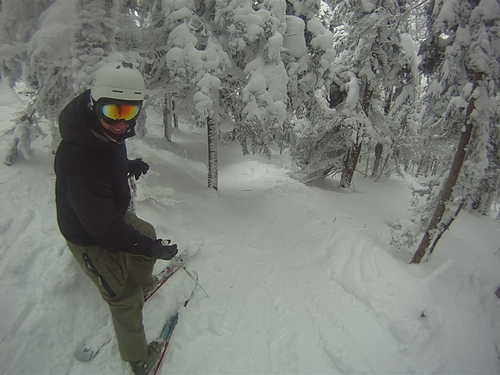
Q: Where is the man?
A: On a mountain.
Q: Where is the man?
A: In the snow.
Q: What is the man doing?
A: Skiing.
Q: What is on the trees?
A: Snow.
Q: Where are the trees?
A: On a mountain.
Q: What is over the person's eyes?
A: Goggles.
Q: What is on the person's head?
A: Helmet.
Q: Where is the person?
A: On snow bank.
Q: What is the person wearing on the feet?
A: Skis.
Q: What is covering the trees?
A: Snow.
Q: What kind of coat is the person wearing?
A: Black snow coat with hood.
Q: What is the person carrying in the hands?
A: Snow poles.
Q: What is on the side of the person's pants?
A: Zippered pockets.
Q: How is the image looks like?
A: Good.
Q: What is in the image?
A: Heap of white snow.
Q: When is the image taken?
A: Snow.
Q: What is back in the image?
A: Tree with snow.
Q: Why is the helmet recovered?
A: Safety.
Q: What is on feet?
A: Skis.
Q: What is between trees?
A: Trail.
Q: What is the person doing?
A: Skiing.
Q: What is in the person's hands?
A: Ski poles.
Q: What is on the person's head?
A: A helmet.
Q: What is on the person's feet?
A: Skis.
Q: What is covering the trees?
A: Snow.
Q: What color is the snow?
A: White.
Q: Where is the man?
A: In the forest.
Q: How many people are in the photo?
A: One.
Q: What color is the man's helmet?
A: White.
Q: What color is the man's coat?
A: Black.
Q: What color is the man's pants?
A: Green.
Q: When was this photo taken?
A: In the winter.